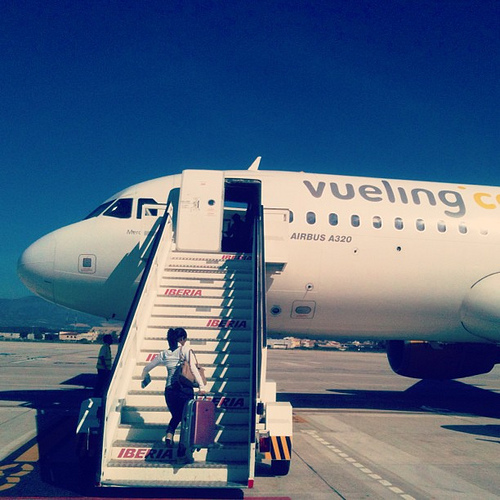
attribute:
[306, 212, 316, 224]
window — small 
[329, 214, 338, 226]
window — small 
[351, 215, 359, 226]
window — small 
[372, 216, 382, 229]
window — small 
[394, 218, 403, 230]
window — small 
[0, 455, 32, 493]
number — painted 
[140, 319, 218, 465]
woman — walking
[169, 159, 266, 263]
door — open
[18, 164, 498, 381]
plane — large 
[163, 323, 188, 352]
hair — black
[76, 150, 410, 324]
airplane — Airbus A320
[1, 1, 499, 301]
sky — clear, blue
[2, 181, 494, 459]
airplane — airport's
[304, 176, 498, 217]
word — gray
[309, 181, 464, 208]
writing — gray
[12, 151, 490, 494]
plane — large , white 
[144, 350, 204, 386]
shirt — white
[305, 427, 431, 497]
line — white , painted , broken 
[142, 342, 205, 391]
shirt — white 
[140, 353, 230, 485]
stairs — portable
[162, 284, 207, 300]
word — red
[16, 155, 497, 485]
airplane — white 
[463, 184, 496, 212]
writing — yellow